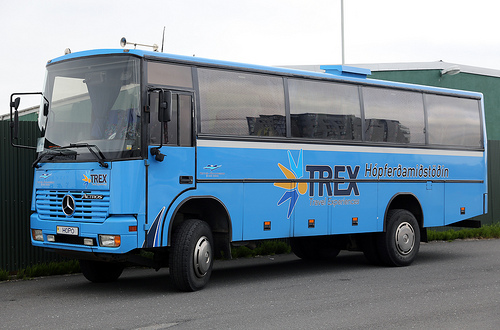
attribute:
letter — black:
[417, 162, 424, 178]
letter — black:
[306, 162, 316, 194]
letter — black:
[322, 165, 333, 198]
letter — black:
[333, 162, 347, 195]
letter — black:
[348, 165, 362, 194]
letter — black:
[393, 160, 403, 181]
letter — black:
[382, 159, 397, 186]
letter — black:
[314, 161, 336, 199]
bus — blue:
[8, 29, 488, 291]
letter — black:
[300, 160, 319, 199]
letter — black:
[368, 166, 378, 181]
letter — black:
[406, 165, 418, 181]